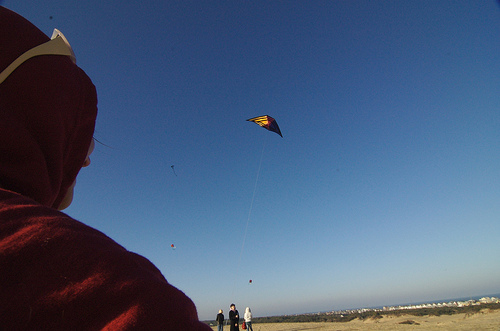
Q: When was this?
A: Daytime.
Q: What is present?
A: A kite.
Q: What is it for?
A: Playing.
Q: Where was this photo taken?
A: At a park.